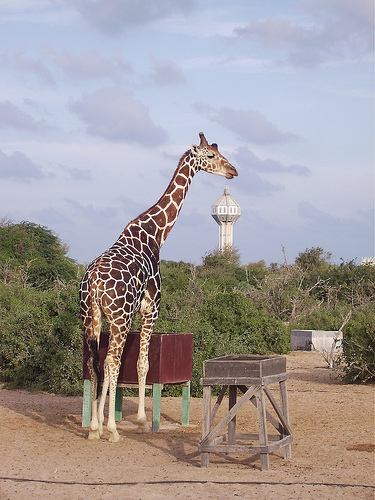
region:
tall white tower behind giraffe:
[207, 180, 252, 257]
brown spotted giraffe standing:
[69, 113, 244, 444]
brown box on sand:
[195, 345, 300, 465]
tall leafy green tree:
[0, 218, 68, 285]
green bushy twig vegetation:
[292, 249, 370, 298]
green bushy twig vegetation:
[186, 266, 284, 303]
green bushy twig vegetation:
[330, 322, 372, 379]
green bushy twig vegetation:
[4, 294, 70, 376]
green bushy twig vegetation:
[166, 300, 256, 356]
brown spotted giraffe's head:
[188, 128, 240, 185]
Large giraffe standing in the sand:
[75, 130, 240, 446]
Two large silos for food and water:
[74, 324, 296, 476]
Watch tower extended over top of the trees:
[207, 180, 243, 262]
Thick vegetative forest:
[1, 220, 374, 386]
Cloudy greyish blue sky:
[1, 1, 374, 262]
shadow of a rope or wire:
[1, 472, 374, 492]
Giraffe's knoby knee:
[131, 352, 151, 380]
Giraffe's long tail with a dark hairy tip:
[86, 269, 106, 408]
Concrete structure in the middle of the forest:
[286, 323, 346, 359]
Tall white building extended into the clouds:
[208, 183, 242, 260]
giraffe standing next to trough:
[58, 132, 235, 436]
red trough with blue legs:
[65, 324, 193, 435]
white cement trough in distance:
[288, 324, 340, 349]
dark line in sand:
[3, 466, 373, 495]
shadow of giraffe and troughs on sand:
[12, 381, 216, 457]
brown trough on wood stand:
[191, 349, 291, 462]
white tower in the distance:
[206, 182, 244, 248]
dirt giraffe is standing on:
[9, 378, 365, 493]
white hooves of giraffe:
[82, 419, 145, 439]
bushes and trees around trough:
[3, 224, 361, 360]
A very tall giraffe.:
[79, 130, 238, 442]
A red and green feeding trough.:
[83, 326, 192, 429]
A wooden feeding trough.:
[199, 352, 292, 468]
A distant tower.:
[209, 182, 241, 260]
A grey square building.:
[289, 326, 343, 352]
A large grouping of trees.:
[0, 219, 374, 396]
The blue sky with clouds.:
[0, 0, 374, 268]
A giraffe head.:
[190, 131, 239, 184]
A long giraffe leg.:
[135, 286, 161, 434]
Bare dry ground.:
[0, 348, 374, 498]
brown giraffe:
[104, 138, 208, 339]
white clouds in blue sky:
[7, 11, 63, 72]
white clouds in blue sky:
[8, 65, 71, 108]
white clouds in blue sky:
[21, 119, 80, 171]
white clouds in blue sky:
[38, 166, 102, 217]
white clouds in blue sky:
[71, 18, 126, 76]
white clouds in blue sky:
[83, 85, 158, 147]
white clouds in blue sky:
[259, 135, 371, 200]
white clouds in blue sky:
[227, 60, 287, 107]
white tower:
[207, 194, 244, 243]